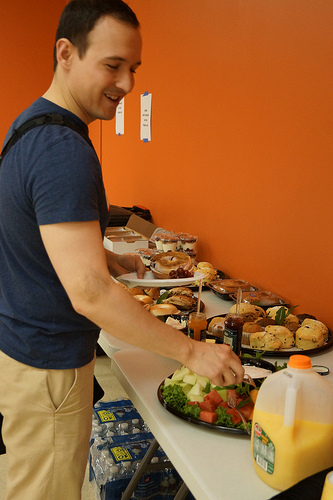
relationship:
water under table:
[82, 397, 167, 500] [104, 219, 332, 499]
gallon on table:
[248, 349, 331, 495] [104, 219, 332, 499]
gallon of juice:
[248, 349, 331, 495] [252, 411, 330, 488]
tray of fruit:
[159, 359, 280, 447] [185, 387, 251, 423]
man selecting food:
[3, 0, 244, 499] [167, 363, 258, 433]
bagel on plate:
[150, 250, 190, 275] [118, 270, 209, 289]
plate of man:
[118, 270, 209, 289] [3, 0, 244, 499]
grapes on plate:
[169, 267, 196, 280] [118, 270, 209, 289]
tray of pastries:
[198, 307, 331, 359] [220, 302, 325, 349]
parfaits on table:
[133, 233, 201, 260] [104, 219, 332, 499]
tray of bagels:
[119, 280, 207, 327] [129, 286, 195, 315]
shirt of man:
[1, 95, 112, 368] [3, 0, 244, 499]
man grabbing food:
[3, 0, 244, 499] [167, 363, 258, 433]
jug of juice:
[248, 349, 331, 495] [252, 411, 330, 488]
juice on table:
[252, 411, 330, 488] [104, 219, 332, 499]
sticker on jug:
[250, 423, 276, 475] [248, 349, 331, 495]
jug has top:
[248, 349, 331, 495] [287, 353, 314, 374]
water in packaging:
[82, 397, 167, 500] [90, 464, 174, 499]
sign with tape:
[135, 89, 157, 149] [141, 138, 149, 143]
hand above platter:
[183, 334, 244, 393] [159, 359, 280, 447]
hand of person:
[183, 334, 244, 393] [3, 0, 244, 499]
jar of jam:
[222, 314, 250, 355] [228, 319, 241, 331]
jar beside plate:
[222, 314, 250, 355] [198, 307, 331, 359]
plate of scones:
[198, 307, 331, 359] [220, 302, 325, 349]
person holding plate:
[3, 0, 244, 499] [118, 270, 209, 289]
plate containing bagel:
[118, 270, 209, 289] [150, 250, 190, 275]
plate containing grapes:
[118, 270, 209, 289] [169, 267, 196, 280]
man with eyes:
[3, 0, 244, 499] [105, 61, 140, 75]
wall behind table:
[104, 5, 331, 331] [104, 219, 332, 499]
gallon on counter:
[248, 349, 331, 495] [104, 219, 332, 499]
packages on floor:
[82, 397, 167, 500] [94, 361, 121, 399]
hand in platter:
[183, 334, 244, 393] [159, 359, 280, 447]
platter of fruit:
[159, 359, 280, 447] [185, 387, 251, 423]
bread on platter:
[220, 302, 325, 349] [198, 307, 331, 359]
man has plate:
[3, 0, 244, 499] [118, 270, 209, 289]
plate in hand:
[118, 270, 209, 289] [110, 255, 155, 280]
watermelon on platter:
[199, 410, 217, 425] [159, 359, 280, 447]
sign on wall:
[135, 89, 157, 149] [104, 5, 331, 331]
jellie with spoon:
[185, 315, 210, 342] [190, 280, 204, 314]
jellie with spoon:
[222, 314, 250, 355] [235, 290, 242, 323]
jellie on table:
[185, 315, 210, 342] [104, 219, 332, 499]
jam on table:
[223, 316, 241, 360] [104, 219, 332, 499]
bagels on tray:
[129, 286, 195, 315] [119, 280, 207, 327]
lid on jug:
[287, 353, 314, 374] [248, 349, 331, 495]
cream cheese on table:
[157, 314, 188, 330] [104, 219, 332, 499]